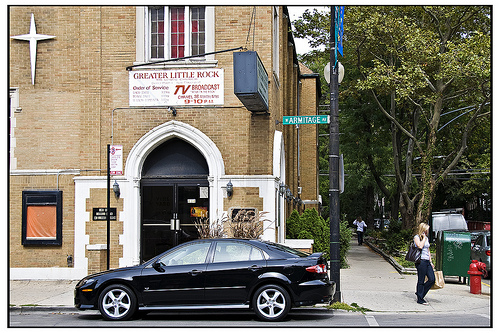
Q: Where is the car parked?
A: By curb.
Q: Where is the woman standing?
A: On the corner.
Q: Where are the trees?
A: Next to sidestreet.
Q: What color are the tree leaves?
A: Green.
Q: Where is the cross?
A: On brick building.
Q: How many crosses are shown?
A: 1.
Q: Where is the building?
A: Behind car.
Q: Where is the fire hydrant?
A: Next to woman.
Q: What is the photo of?
A: A car.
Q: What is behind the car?
A: A church.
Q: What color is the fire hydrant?
A: Red.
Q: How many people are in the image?
A: Two.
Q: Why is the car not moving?
A: It's parked.